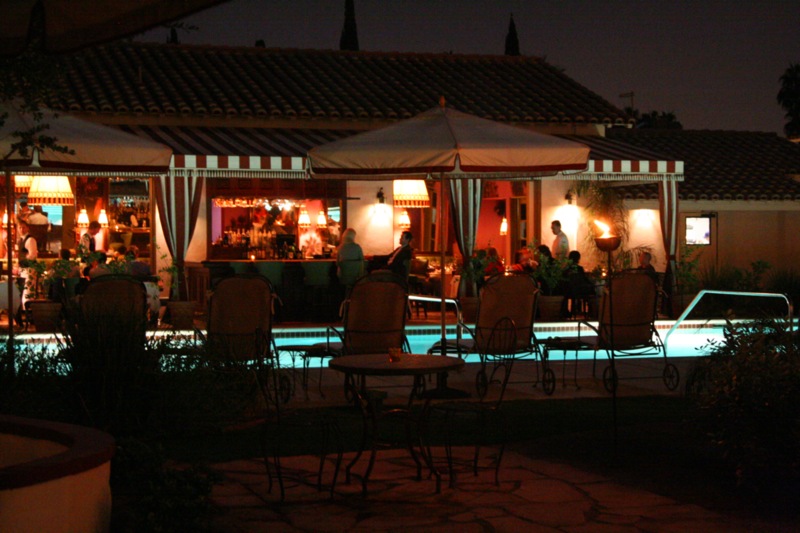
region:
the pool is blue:
[21, 314, 799, 372]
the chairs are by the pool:
[86, 279, 650, 368]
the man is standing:
[545, 219, 563, 256]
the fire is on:
[592, 219, 613, 249]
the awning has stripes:
[150, 145, 684, 259]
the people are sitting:
[327, 223, 413, 289]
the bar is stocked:
[216, 203, 299, 257]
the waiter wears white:
[81, 231, 93, 251]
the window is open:
[686, 207, 712, 248]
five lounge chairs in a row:
[32, 260, 669, 500]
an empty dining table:
[304, 341, 529, 502]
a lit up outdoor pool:
[3, 320, 795, 364]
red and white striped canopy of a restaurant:
[130, 115, 676, 287]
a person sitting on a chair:
[331, 221, 364, 286]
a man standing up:
[544, 209, 576, 261]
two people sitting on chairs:
[324, 219, 415, 283]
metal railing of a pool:
[658, 281, 789, 349]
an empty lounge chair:
[540, 258, 674, 374]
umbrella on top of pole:
[300, 97, 593, 186]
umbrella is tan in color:
[276, 87, 621, 187]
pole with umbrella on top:
[402, 176, 486, 334]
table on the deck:
[314, 342, 476, 494]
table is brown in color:
[332, 337, 477, 493]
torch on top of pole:
[591, 215, 624, 259]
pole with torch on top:
[594, 246, 634, 450]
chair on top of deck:
[463, 273, 552, 388]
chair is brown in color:
[444, 272, 552, 388]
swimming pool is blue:
[6, 318, 792, 350]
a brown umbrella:
[285, 96, 608, 187]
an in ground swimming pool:
[0, 330, 798, 364]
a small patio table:
[329, 338, 475, 477]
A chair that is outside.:
[304, 277, 417, 386]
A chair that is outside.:
[425, 280, 534, 382]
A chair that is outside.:
[540, 266, 690, 392]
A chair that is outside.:
[185, 265, 279, 390]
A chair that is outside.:
[65, 256, 170, 389]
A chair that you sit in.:
[188, 282, 300, 375]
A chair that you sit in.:
[308, 282, 402, 380]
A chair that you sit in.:
[436, 282, 541, 379]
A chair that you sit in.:
[550, 267, 681, 374]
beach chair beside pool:
[534, 262, 690, 371]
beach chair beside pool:
[538, 255, 685, 380]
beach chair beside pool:
[524, 250, 687, 383]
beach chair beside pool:
[531, 251, 687, 373]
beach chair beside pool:
[529, 229, 699, 375]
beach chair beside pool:
[521, 250, 694, 375]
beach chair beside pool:
[509, 240, 694, 382]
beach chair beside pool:
[520, 250, 690, 367]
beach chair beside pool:
[520, 242, 684, 379]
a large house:
[8, 64, 788, 320]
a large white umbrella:
[312, 101, 589, 179]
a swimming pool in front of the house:
[13, 305, 799, 349]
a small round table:
[328, 353, 459, 489]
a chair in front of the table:
[434, 329, 512, 478]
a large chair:
[209, 277, 273, 382]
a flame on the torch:
[593, 214, 620, 248]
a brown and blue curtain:
[152, 160, 208, 313]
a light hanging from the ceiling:
[25, 173, 71, 203]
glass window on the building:
[693, 226, 704, 242]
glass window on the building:
[696, 212, 712, 228]